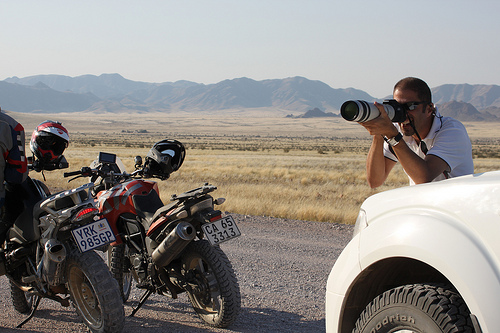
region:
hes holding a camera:
[341, 67, 441, 181]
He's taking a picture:
[316, 81, 464, 201]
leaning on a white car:
[365, 133, 457, 272]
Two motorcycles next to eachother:
[5, 131, 249, 316]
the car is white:
[359, 172, 493, 259]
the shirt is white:
[442, 114, 465, 174]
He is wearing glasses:
[387, 93, 432, 118]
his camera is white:
[336, 93, 397, 127]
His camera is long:
[342, 102, 405, 124]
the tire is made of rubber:
[378, 280, 445, 332]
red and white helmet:
[32, 117, 73, 171]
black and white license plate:
[65, 226, 119, 254]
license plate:
[200, 209, 235, 255]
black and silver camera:
[347, 83, 387, 134]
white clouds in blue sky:
[13, 16, 45, 56]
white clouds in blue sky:
[56, 13, 100, 51]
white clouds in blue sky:
[129, 23, 151, 55]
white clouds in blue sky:
[185, 6, 227, 57]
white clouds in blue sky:
[216, 19, 247, 54]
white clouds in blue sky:
[246, 13, 304, 62]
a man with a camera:
[337, 63, 451, 168]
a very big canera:
[329, 82, 425, 132]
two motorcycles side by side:
[10, 135, 283, 317]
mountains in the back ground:
[24, 50, 394, 118]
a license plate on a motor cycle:
[66, 208, 131, 291]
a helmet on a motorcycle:
[130, 116, 217, 177]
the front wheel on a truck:
[349, 237, 498, 330]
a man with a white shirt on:
[354, 67, 486, 185]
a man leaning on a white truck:
[313, 72, 498, 324]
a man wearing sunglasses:
[393, 73, 450, 135]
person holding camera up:
[317, 58, 484, 199]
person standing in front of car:
[308, 68, 492, 330]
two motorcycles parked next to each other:
[2, 96, 267, 331]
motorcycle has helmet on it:
[75, 113, 225, 252]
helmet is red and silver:
[19, 88, 85, 185]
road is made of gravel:
[188, 160, 337, 322]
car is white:
[286, 138, 494, 328]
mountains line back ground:
[16, 30, 491, 180]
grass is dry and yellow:
[164, 122, 361, 240]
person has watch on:
[346, 65, 462, 196]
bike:
[60, 120, 260, 327]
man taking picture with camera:
[330, 70, 462, 178]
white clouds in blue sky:
[21, 12, 90, 56]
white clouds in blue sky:
[98, 15, 151, 68]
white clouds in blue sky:
[146, 8, 187, 63]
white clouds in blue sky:
[233, 4, 256, 66]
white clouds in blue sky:
[258, 0, 291, 55]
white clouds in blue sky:
[296, 12, 326, 67]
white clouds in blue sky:
[349, 24, 407, 90]